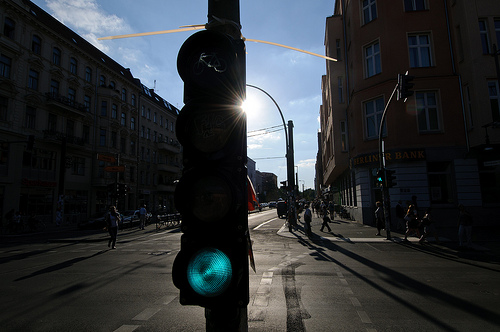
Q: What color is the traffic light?
A: Green.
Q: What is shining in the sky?
A: Sun.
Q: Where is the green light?
A: On the traffic light.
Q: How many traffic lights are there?
A: 1.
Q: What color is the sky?
A: Blue.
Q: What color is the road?
A: Black.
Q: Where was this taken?
A: On a street.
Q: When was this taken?
A: Daytime.